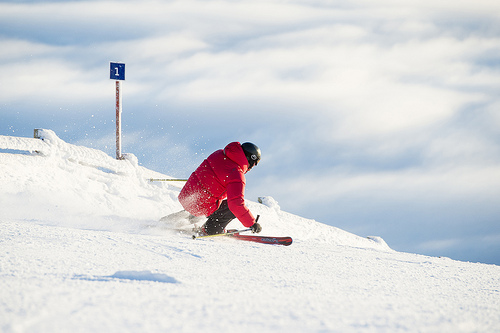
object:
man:
[176, 141, 263, 239]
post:
[115, 80, 121, 160]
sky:
[0, 0, 500, 265]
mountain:
[0, 127, 499, 331]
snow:
[42, 224, 316, 327]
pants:
[187, 199, 236, 236]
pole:
[192, 215, 262, 241]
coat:
[177, 141, 256, 228]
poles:
[151, 178, 188, 183]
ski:
[142, 224, 292, 247]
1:
[113, 67, 121, 76]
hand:
[249, 222, 262, 233]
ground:
[0, 129, 500, 333]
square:
[110, 62, 126, 80]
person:
[177, 141, 261, 237]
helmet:
[241, 142, 262, 169]